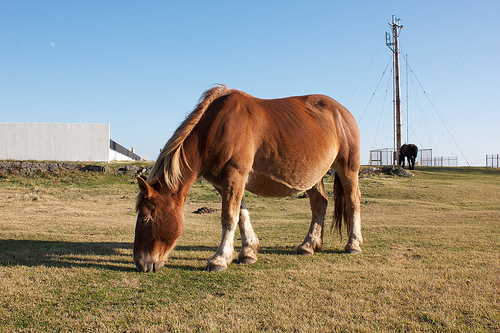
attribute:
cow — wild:
[394, 141, 419, 166]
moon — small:
[46, 39, 58, 49]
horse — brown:
[129, 92, 362, 260]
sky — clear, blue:
[67, 40, 177, 85]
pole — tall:
[356, 24, 425, 165]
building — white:
[8, 103, 135, 166]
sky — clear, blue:
[1, 1, 470, 126]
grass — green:
[16, 259, 134, 331]